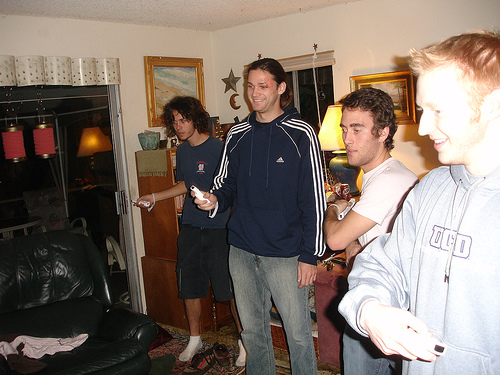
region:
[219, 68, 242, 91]
A star on the wall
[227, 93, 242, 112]
A moon on the wall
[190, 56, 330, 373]
A man in a dark blue shirt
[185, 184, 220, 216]
A controller in the man's hand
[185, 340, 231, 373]
A pair of shoes on the floor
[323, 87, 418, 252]
A man in a white shirt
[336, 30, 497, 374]
A man in a hoodie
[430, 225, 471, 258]
Writing on the hoodie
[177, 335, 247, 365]
The man's white socks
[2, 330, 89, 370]
Clothing crumpled on a chair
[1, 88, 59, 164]
red adn gold light fixtures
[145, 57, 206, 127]
painting in a gold frame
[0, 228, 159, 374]
green leather chair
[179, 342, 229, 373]
pair of shoes sitting on the floor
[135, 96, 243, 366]
a man standing holding a Nintendo Wii controller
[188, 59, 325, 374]
a man holding a Nintendo Wii controller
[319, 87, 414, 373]
a man holding a Nintendo Wii controller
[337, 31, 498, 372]
a man holding a Nintendo Wii controller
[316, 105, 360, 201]
a blue lamp with a white shade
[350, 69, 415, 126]
painting in a gold frame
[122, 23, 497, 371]
Four guys are playing video games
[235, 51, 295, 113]
A guy is smiling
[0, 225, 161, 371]
A black leather chair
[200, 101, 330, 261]
White stripes on a navy blue sweatshirt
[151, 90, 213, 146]
Guy has long brown hair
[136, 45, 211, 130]
Painting on the wall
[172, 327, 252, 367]
A pair of white socks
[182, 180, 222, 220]
Game controller in a hand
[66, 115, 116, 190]
Lamp's reflection on glass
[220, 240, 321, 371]
A pair of blue jeans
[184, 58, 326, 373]
man in blue shirt holding wii remote controller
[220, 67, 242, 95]
brown star hanging on wall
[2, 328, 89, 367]
white tee shirt strewn on couch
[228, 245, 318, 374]
pair of light blue jeans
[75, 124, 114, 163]
reflection of lamp shade in sliding glass door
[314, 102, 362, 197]
blue lamp with tan shade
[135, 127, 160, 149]
blue and lavender ceramic bowl on top of shelf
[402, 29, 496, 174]
short red hair on man's head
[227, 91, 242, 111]
brown crescent moon hanging on wall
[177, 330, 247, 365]
pair of white ankle socks on feet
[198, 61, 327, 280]
man in blue and white sweater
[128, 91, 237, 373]
man in blue with white wii controller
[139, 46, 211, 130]
painting on wall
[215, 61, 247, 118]
star and moon on wall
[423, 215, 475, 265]
ucd on gray sweater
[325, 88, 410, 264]
man in white t-shirt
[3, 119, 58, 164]
red lanterns on wall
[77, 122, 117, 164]
lamp on wall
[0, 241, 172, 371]
black chair on wall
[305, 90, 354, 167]
lit lamp behind men